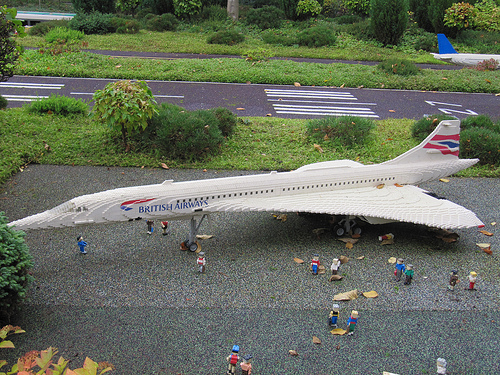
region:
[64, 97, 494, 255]
long and white plane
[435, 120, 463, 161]
red and blue tail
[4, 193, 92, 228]
white nose on plane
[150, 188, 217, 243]
blue logo on plane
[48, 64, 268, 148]
green bushes behind plane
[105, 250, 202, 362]
tarmac is light grey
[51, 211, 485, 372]
small figures next to plane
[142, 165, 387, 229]
long row of small windows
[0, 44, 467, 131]
white lines on runway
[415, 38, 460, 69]
plane in rear has blue tail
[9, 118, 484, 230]
a Lego Concorde airplane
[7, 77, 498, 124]
a make believe runway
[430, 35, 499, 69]
tail of a plane in he distance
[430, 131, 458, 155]
British Airways logo on Concorde tail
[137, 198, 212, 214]
British Airways in blue on plane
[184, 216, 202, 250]
front landing gear on plane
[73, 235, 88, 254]
figurine in blue under nose of airplane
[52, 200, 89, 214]
cockpit of model airplane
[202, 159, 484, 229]
wings of the model airplane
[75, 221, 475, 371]
several Lego people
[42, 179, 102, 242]
the front of a plane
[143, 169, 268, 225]
the windows on a plane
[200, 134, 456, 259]
the wing on a plane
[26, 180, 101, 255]
the nose of a plane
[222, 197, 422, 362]
people around a plane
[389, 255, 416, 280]
the head of a person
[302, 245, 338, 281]
the body of a man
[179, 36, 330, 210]
a road near a plane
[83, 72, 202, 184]
a tree near a plane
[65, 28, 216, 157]
green leaves on a tree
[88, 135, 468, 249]
this is a plane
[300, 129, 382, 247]
the plane is made of legos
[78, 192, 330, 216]
this is a british airways plane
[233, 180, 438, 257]
this is a wing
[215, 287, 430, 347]
this is a bunch of people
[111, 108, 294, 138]
these are some bushes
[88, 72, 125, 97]
this is a long line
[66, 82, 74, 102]
the line is white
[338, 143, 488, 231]
this is a tail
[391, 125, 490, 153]
the tail is red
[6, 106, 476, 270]
model airplane made of legos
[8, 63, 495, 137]
model runway with white markings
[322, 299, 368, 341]
pair of model spectators looking at plane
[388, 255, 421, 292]
pair of model spectators looking at plane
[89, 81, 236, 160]
model tree and brush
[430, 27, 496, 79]
tail of model plane made of legos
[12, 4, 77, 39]
small building in the distance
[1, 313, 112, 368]
yellow and red leaves on the ground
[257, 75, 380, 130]
straight white lines on asphalt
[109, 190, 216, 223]
red and blue logo on lego plane